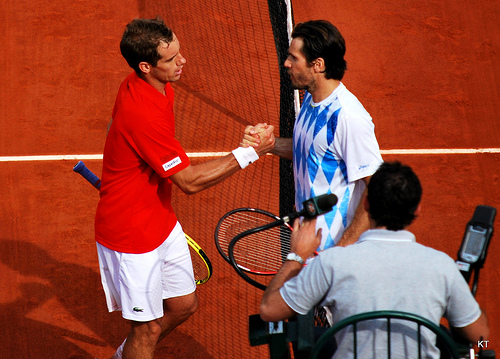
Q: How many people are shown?
A: Three.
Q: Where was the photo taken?
A: Tennis court.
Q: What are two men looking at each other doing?
A: Shaking hands.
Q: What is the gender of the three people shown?
A: Male.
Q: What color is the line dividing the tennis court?
A: White.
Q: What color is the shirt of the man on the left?
A: Red.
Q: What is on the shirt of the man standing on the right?
A: Diamonds.